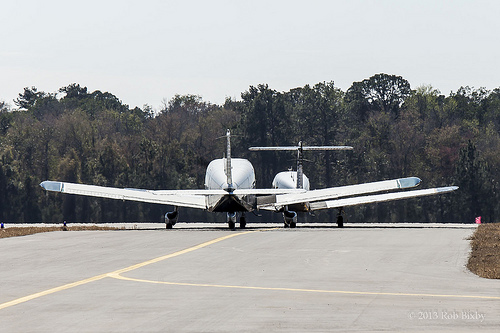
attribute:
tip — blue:
[35, 167, 73, 205]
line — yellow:
[2, 227, 258, 312]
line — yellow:
[110, 271, 499, 303]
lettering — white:
[408, 305, 486, 325]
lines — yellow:
[2, 264, 496, 331]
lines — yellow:
[12, 235, 444, 313]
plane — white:
[39, 127, 421, 229]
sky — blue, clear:
[32, 8, 487, 99]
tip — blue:
[395, 172, 423, 191]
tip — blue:
[433, 180, 457, 192]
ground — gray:
[0, 216, 499, 329]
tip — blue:
[392, 176, 424, 199]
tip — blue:
[32, 176, 66, 197]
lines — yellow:
[10, 236, 495, 330]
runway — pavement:
[2, 227, 498, 330]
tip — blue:
[41, 174, 62, 201]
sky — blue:
[1, 7, 499, 116]